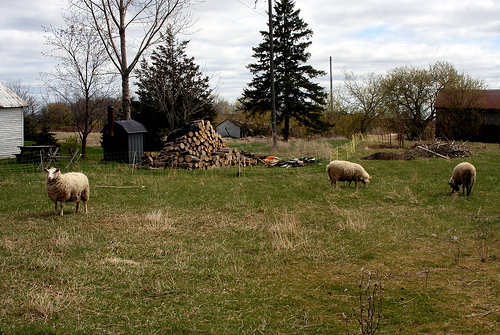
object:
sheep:
[324, 159, 371, 190]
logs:
[149, 134, 191, 149]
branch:
[220, 101, 433, 140]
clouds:
[0, 0, 495, 104]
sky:
[1, 0, 498, 111]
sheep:
[41, 166, 91, 214]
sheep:
[444, 162, 475, 199]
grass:
[0, 130, 498, 333]